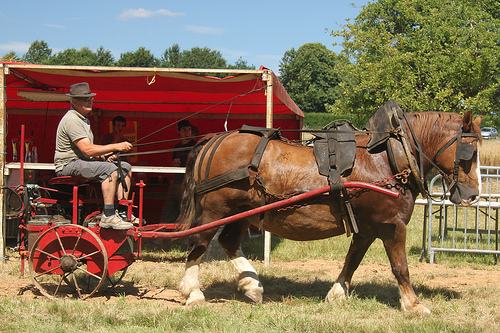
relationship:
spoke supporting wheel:
[76, 249, 100, 261] [27, 223, 110, 305]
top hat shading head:
[61, 81, 97, 99] [69, 89, 93, 115]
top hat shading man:
[61, 81, 97, 99] [52, 81, 143, 231]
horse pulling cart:
[180, 109, 479, 315] [23, 173, 140, 303]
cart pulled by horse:
[18, 174, 146, 297] [180, 109, 479, 315]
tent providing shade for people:
[2, 57, 302, 217] [103, 115, 203, 170]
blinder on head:
[455, 140, 473, 159] [438, 110, 483, 207]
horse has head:
[180, 109, 479, 315] [438, 110, 483, 207]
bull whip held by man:
[129, 85, 280, 142] [52, 81, 143, 231]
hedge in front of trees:
[306, 113, 481, 138] [279, 1, 485, 111]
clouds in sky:
[112, 5, 228, 36] [0, 4, 322, 40]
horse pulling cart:
[180, 109, 479, 315] [13, 175, 148, 304]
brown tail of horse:
[170, 144, 203, 233] [180, 109, 479, 315]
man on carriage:
[52, 81, 143, 231] [21, 165, 170, 299]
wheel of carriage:
[30, 224, 108, 301] [15, 175, 159, 304]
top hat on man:
[61, 83, 99, 102] [52, 81, 143, 231]